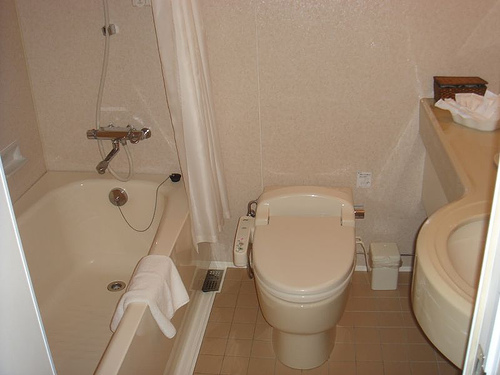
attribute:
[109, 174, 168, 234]
chain — metal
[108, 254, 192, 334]
mat — cloth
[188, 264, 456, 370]
tile — brown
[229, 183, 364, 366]
toilet — white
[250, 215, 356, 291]
lid — down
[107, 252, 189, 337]
towel — white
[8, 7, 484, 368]
bathroom — clean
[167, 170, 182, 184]
stopper — black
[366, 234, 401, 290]
trash can — plastic, white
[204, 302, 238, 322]
tile — tan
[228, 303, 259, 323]
tile — tan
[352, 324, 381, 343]
tile — tan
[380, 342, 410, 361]
tile — tan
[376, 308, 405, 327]
tile — tan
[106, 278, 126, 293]
tub drain — silver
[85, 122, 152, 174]
tub faucet — silver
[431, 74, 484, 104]
container — brown, wicker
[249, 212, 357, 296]
toilet lid — plastic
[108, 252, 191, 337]
hand towel — white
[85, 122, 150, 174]
faucet — silver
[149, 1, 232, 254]
shower curtain — white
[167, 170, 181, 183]
drain plug — black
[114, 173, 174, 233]
chain — metal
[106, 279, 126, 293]
drain — silver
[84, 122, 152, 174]
water control — silver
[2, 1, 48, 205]
wall — tile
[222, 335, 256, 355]
tile — tan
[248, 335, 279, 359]
tile — tan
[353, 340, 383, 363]
tile — tan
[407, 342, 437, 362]
tile — tan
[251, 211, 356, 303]
toilet seat — white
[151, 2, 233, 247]
curtain — white